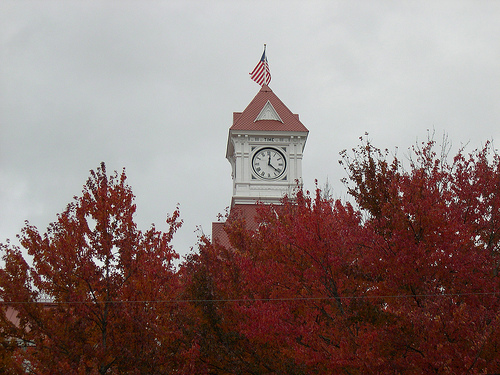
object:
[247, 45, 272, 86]
flag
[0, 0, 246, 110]
sky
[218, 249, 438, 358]
tree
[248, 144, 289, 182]
clock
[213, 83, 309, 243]
building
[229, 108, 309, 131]
roof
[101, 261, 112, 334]
branch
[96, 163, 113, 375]
trees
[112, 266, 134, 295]
branches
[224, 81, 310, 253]
tower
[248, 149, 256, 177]
border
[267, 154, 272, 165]
hands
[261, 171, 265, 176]
numbers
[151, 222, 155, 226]
leaves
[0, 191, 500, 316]
season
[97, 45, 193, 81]
cloud